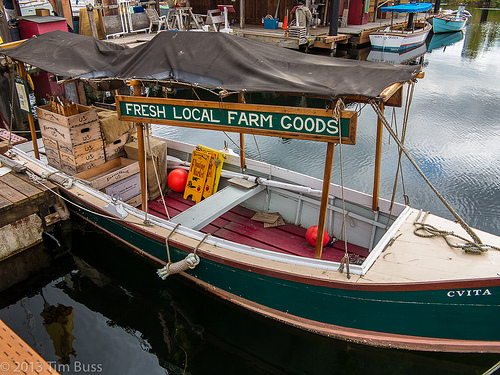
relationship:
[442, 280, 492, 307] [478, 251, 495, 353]
name on bow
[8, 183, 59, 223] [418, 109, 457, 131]
dock on water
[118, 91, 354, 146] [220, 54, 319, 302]
advertisement on boat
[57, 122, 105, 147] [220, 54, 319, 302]
crates in boat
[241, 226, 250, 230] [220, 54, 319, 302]
deck of boat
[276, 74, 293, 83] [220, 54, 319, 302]
tarp on boat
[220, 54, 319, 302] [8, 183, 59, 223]
boat by dock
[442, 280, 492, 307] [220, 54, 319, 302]
name of boat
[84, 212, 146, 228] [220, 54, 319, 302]
ropes on boat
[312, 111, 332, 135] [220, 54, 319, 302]
sign on boat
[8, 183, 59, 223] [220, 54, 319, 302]
dock on boat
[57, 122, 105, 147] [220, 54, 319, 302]
crates on boat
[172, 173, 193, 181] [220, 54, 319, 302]
bumper on boat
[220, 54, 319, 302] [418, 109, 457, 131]
boat on water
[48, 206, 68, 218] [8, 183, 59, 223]
steps on dock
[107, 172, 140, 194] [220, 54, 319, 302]
planks in boat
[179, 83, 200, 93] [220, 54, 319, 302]
roof of boat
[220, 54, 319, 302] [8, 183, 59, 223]
boat on dock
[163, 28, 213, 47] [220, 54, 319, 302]
tent of boat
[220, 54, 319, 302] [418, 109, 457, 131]
boat in water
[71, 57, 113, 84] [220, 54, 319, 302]
canopy on boat